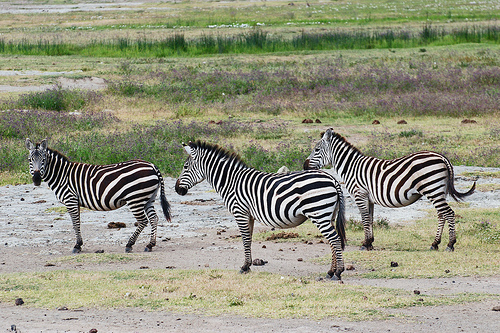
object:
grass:
[0, 25, 499, 60]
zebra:
[25, 138, 172, 254]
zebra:
[175, 139, 347, 281]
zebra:
[303, 127, 476, 252]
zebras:
[25, 128, 475, 281]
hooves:
[238, 269, 340, 281]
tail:
[139, 160, 172, 222]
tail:
[311, 170, 347, 250]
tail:
[429, 152, 476, 202]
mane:
[35, 143, 70, 162]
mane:
[189, 139, 249, 168]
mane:
[319, 130, 363, 153]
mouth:
[174, 187, 188, 197]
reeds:
[1, 21, 500, 57]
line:
[25, 128, 475, 280]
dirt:
[0, 173, 498, 332]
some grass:
[0, 55, 500, 117]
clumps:
[23, 128, 476, 281]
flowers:
[0, 108, 124, 139]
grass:
[0, 267, 499, 322]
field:
[1, 1, 500, 333]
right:
[1, 0, 177, 332]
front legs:
[64, 201, 83, 254]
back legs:
[125, 205, 159, 253]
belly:
[250, 207, 306, 229]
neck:
[203, 146, 233, 206]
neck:
[49, 150, 71, 203]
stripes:
[64, 165, 144, 203]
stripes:
[241, 175, 310, 215]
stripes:
[358, 160, 416, 199]